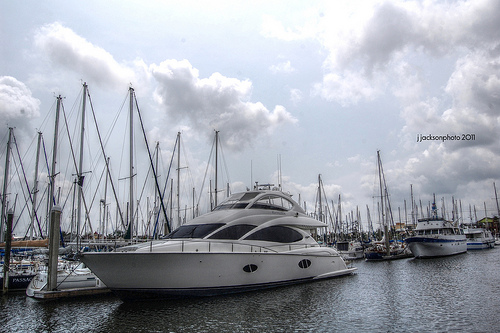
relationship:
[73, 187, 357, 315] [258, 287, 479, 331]
yacht in water